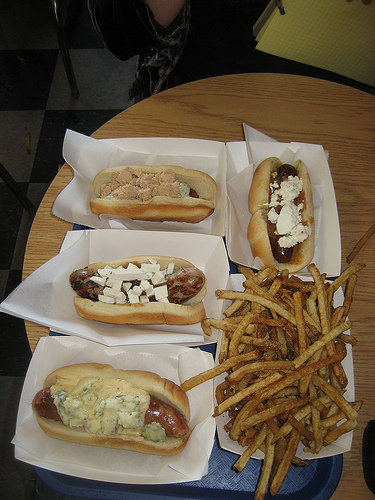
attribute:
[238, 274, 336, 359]
french fries — bunched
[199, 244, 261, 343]
container — paper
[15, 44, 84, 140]
tile — black, white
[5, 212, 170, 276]
paper — container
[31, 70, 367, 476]
table — wood, laminate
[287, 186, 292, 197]
garnish — white 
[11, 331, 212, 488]
container — paper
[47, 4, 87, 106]
chair leg — silver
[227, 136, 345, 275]
container — paper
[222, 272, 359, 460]
container — side